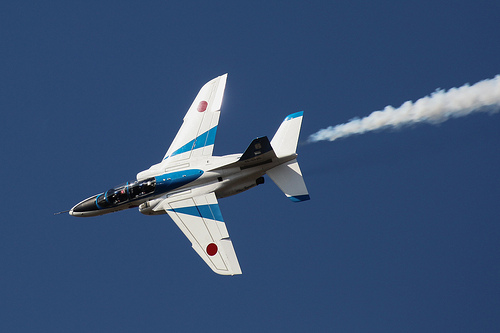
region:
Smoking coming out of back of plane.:
[333, 98, 445, 140]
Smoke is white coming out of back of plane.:
[323, 85, 451, 142]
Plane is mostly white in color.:
[78, 132, 388, 247]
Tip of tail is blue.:
[276, 185, 321, 206]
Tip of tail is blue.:
[280, 98, 313, 125]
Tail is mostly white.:
[256, 107, 331, 239]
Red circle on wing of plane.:
[192, 235, 257, 277]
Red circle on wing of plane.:
[192, 90, 237, 133]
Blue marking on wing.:
[170, 195, 260, 245]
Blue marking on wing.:
[162, 125, 273, 153]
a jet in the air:
[67, 69, 321, 281]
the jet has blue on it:
[151, 168, 208, 198]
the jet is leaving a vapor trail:
[313, 65, 498, 159]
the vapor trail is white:
[316, 63, 499, 146]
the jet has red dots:
[189, 233, 234, 261]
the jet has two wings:
[153, 36, 243, 288]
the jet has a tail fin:
[239, 123, 279, 172]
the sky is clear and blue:
[1, 0, 480, 69]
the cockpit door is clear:
[84, 179, 159, 209]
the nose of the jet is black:
[71, 196, 94, 218]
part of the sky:
[435, 259, 451, 277]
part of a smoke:
[383, 107, 388, 177]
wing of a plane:
[215, 231, 226, 281]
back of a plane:
[288, 158, 300, 183]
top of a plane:
[146, 173, 157, 190]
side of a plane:
[195, 208, 208, 240]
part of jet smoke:
[386, 52, 398, 127]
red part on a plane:
[210, 235, 216, 249]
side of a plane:
[188, 107, 200, 113]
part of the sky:
[348, 222, 395, 281]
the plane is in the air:
[68, 72, 310, 275]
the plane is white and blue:
[69, 72, 310, 272]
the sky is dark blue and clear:
[0, 0, 496, 330]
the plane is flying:
[1, 0, 497, 330]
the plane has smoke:
[305, 81, 496, 143]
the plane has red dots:
[197, 98, 217, 254]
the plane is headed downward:
[66, 70, 306, 271]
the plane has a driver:
[110, 187, 125, 202]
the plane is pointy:
[66, 165, 197, 213]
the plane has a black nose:
[72, 192, 109, 215]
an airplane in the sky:
[49, 27, 433, 307]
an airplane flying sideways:
[62, 4, 349, 326]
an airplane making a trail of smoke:
[64, 50, 493, 253]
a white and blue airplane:
[21, 35, 433, 316]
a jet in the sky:
[34, 38, 404, 314]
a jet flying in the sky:
[39, 27, 461, 289]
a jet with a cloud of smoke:
[47, 32, 499, 264]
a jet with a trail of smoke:
[12, 6, 486, 314]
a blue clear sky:
[289, 200, 458, 331]